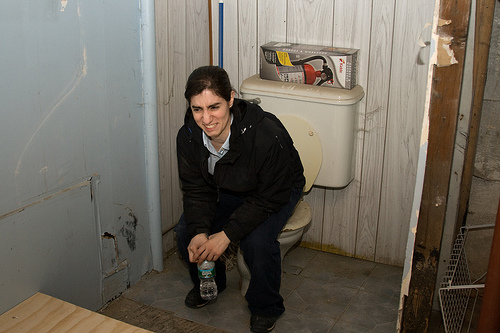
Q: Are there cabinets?
A: No, there are no cabinets.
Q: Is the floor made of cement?
A: Yes, the floor is made of cement.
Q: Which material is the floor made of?
A: The floor is made of cement.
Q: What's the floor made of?
A: The floor is made of concrete.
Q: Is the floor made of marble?
A: No, the floor is made of concrete.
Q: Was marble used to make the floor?
A: No, the floor is made of concrete.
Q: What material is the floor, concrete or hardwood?
A: The floor is made of concrete.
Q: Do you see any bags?
A: No, there are no bags.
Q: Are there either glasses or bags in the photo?
A: No, there are no bags or glasses.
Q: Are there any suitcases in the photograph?
A: No, there are no suitcases.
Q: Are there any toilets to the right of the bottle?
A: Yes, there is a toilet to the right of the bottle.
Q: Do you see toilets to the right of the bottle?
A: Yes, there is a toilet to the right of the bottle.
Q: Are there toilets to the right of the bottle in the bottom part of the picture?
A: Yes, there is a toilet to the right of the bottle.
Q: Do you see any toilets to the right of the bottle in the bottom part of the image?
A: Yes, there is a toilet to the right of the bottle.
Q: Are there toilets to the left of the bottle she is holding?
A: No, the toilet is to the right of the bottle.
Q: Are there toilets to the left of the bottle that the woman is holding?
A: No, the toilet is to the right of the bottle.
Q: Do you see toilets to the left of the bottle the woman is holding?
A: No, the toilet is to the right of the bottle.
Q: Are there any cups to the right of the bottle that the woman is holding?
A: No, there is a toilet to the right of the bottle.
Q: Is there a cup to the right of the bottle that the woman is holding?
A: No, there is a toilet to the right of the bottle.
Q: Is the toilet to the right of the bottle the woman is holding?
A: Yes, the toilet is to the right of the bottle.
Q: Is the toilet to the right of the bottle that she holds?
A: Yes, the toilet is to the right of the bottle.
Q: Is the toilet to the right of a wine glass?
A: No, the toilet is to the right of the bottle.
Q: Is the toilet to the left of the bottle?
A: No, the toilet is to the right of the bottle.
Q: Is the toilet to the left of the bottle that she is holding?
A: No, the toilet is to the right of the bottle.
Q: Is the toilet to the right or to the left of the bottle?
A: The toilet is to the right of the bottle.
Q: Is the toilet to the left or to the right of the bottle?
A: The toilet is to the right of the bottle.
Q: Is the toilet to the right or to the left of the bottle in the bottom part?
A: The toilet is to the right of the bottle.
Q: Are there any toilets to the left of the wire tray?
A: Yes, there is a toilet to the left of the tray.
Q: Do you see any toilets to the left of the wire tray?
A: Yes, there is a toilet to the left of the tray.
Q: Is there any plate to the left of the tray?
A: No, there is a toilet to the left of the tray.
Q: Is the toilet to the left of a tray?
A: Yes, the toilet is to the left of a tray.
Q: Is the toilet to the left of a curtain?
A: No, the toilet is to the left of a tray.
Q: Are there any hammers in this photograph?
A: No, there are no hammers.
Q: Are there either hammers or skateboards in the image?
A: No, there are no hammers or skateboards.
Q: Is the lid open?
A: Yes, the lid is open.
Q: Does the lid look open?
A: Yes, the lid is open.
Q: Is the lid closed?
A: No, the lid is open.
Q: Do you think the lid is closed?
A: No, the lid is open.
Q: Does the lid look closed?
A: No, the lid is open.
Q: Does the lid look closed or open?
A: The lid is open.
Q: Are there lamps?
A: No, there are no lamps.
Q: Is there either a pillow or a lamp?
A: No, there are no lamps or pillows.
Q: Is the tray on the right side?
A: Yes, the tray is on the right of the image.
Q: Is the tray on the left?
A: No, the tray is on the right of the image.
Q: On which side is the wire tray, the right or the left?
A: The tray is on the right of the image.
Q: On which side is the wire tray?
A: The tray is on the right of the image.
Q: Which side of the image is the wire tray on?
A: The tray is on the right of the image.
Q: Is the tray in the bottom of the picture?
A: Yes, the tray is in the bottom of the image.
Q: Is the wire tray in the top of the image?
A: No, the tray is in the bottom of the image.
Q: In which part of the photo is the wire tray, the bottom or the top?
A: The tray is in the bottom of the image.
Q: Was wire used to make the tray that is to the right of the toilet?
A: Yes, the tray is made of wire.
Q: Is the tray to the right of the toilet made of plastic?
A: No, the tray is made of wire.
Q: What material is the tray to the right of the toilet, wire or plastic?
A: The tray is made of wire.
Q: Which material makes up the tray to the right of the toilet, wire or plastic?
A: The tray is made of wire.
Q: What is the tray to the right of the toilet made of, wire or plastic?
A: The tray is made of wire.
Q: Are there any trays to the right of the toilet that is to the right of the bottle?
A: Yes, there is a tray to the right of the toilet.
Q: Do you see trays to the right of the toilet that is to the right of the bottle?
A: Yes, there is a tray to the right of the toilet.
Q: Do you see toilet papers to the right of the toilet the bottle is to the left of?
A: No, there is a tray to the right of the toilet.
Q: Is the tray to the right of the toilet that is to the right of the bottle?
A: Yes, the tray is to the right of the toilet.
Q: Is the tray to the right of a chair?
A: No, the tray is to the right of the toilet.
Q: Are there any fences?
A: No, there are no fences.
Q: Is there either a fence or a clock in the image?
A: No, there are no fences or clocks.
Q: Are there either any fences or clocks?
A: No, there are no fences or clocks.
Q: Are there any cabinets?
A: No, there are no cabinets.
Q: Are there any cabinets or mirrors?
A: No, there are no cabinets or mirrors.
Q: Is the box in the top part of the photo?
A: Yes, the box is in the top of the image.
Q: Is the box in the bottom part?
A: No, the box is in the top of the image.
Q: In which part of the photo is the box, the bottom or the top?
A: The box is in the top of the image.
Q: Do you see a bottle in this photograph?
A: Yes, there is a bottle.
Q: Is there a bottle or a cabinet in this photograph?
A: Yes, there is a bottle.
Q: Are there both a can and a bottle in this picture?
A: No, there is a bottle but no cans.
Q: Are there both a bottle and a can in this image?
A: No, there is a bottle but no cans.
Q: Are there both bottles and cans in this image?
A: No, there is a bottle but no cans.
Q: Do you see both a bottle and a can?
A: No, there is a bottle but no cans.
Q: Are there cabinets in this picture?
A: No, there are no cabinets.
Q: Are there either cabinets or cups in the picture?
A: No, there are no cabinets or cups.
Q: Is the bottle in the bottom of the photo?
A: Yes, the bottle is in the bottom of the image.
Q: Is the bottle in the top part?
A: No, the bottle is in the bottom of the image.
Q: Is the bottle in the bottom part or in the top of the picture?
A: The bottle is in the bottom of the image.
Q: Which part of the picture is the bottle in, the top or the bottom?
A: The bottle is in the bottom of the image.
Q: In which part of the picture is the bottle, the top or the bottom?
A: The bottle is in the bottom of the image.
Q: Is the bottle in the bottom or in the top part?
A: The bottle is in the bottom of the image.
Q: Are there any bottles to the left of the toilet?
A: Yes, there is a bottle to the left of the toilet.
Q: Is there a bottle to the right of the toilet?
A: No, the bottle is to the left of the toilet.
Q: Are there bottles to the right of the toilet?
A: No, the bottle is to the left of the toilet.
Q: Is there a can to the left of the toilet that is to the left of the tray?
A: No, there is a bottle to the left of the toilet.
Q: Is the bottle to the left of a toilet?
A: Yes, the bottle is to the left of a toilet.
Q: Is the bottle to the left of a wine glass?
A: No, the bottle is to the left of a toilet.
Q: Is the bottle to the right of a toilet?
A: No, the bottle is to the left of a toilet.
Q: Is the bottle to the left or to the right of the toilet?
A: The bottle is to the left of the toilet.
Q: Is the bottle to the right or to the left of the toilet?
A: The bottle is to the left of the toilet.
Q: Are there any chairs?
A: No, there are no chairs.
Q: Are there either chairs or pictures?
A: No, there are no chairs or pictures.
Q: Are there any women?
A: Yes, there is a woman.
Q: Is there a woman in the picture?
A: Yes, there is a woman.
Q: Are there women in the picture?
A: Yes, there is a woman.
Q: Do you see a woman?
A: Yes, there is a woman.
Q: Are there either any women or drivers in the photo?
A: Yes, there is a woman.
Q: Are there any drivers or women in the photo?
A: Yes, there is a woman.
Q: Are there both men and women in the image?
A: No, there is a woman but no men.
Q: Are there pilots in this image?
A: No, there are no pilots.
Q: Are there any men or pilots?
A: No, there are no pilots or men.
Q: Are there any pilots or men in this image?
A: No, there are no pilots or men.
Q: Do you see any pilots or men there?
A: No, there are no pilots or men.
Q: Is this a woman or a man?
A: This is a woman.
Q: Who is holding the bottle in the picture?
A: The woman is holding the bottle.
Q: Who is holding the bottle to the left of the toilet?
A: The woman is holding the bottle.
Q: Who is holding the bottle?
A: The woman is holding the bottle.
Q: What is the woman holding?
A: The woman is holding the bottle.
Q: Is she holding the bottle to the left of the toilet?
A: Yes, the woman is holding the bottle.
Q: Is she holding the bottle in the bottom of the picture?
A: Yes, the woman is holding the bottle.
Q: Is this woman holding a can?
A: No, the woman is holding the bottle.